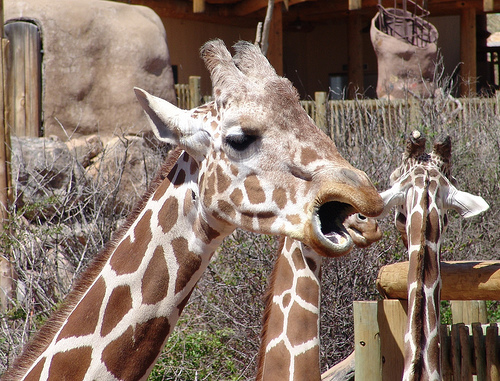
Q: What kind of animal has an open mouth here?
A: Giraffe.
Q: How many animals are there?
A: Three.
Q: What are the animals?
A: Giraffes.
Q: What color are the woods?
A: Grey.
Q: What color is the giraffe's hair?
A: Brown.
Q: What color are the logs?
A: Brown.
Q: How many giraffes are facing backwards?
A: One.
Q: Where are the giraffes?
A: In a park.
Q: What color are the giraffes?
A: Brown.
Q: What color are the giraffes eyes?
A: Black.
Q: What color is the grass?
A: Green.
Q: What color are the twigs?
A: Brown.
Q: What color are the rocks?
A: Gray.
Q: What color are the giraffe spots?
A: Brown.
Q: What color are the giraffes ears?
A: Brown.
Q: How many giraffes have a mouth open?
A: One.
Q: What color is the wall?
A: Brown.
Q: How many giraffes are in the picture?
A: Three.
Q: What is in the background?
A: Building.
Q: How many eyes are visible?
A: One.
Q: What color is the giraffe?
A: Brown and white.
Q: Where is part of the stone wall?
A: Behind the giraffes.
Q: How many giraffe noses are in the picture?
A: Two.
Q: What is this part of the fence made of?
A: Wood.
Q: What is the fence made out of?
A: Wood.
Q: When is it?
A: Daytime.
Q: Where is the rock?
A: Behind the giraffe.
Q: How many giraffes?
A: 3.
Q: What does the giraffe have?
A: Fur.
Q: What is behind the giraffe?
A: Fence.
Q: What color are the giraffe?
A: Brown.